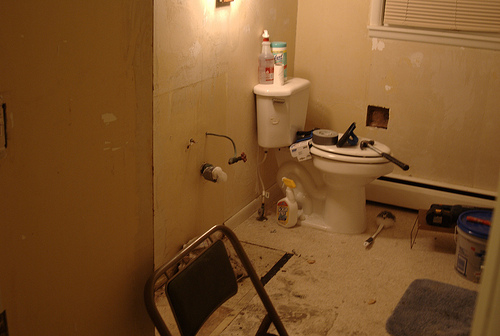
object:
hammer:
[359, 138, 410, 171]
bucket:
[454, 210, 494, 283]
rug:
[386, 278, 478, 335]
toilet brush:
[363, 209, 396, 248]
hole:
[366, 104, 390, 130]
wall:
[294, 0, 500, 213]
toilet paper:
[274, 62, 286, 88]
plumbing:
[200, 133, 248, 184]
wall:
[153, 0, 299, 280]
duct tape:
[311, 129, 340, 145]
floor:
[155, 207, 482, 335]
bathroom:
[1, 0, 500, 334]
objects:
[258, 28, 311, 150]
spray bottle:
[276, 176, 297, 227]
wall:
[1, 1, 157, 335]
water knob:
[241, 151, 248, 163]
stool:
[144, 223, 291, 336]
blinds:
[384, 0, 500, 32]